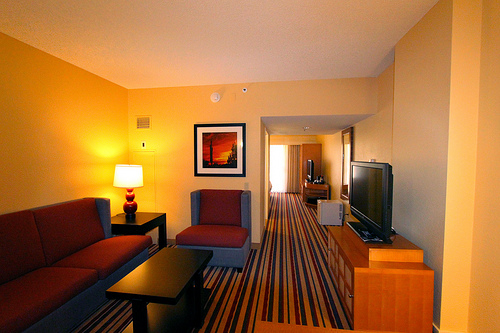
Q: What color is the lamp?
A: Yellow.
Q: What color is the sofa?
A: Red and gray.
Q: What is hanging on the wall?
A: A picture.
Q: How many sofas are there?
A: One.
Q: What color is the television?
A: Black.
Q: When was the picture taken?
A: Daytime.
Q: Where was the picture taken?
A: In a living room of a home.